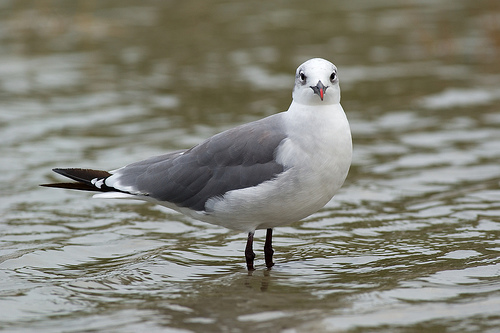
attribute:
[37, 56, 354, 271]
bird — gray, white, black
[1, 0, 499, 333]
water — brown, choppy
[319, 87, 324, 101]
beak — orange, red, black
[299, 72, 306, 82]
eye — black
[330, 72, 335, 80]
eye — black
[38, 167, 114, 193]
tail — black, white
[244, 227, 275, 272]
legs — black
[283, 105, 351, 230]
chest — white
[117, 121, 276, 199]
wing — gray, grey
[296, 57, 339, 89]
bird head — white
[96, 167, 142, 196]
feathers — white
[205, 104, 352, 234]
breast plumage — white